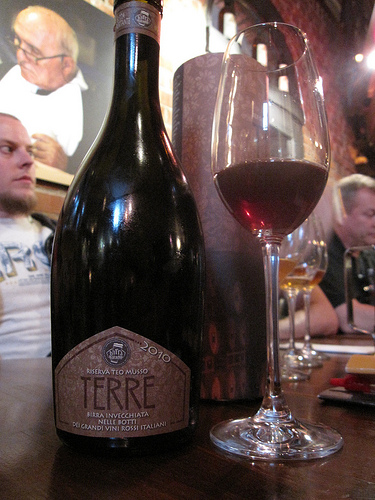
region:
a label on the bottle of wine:
[53, 331, 193, 437]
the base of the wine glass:
[213, 408, 344, 458]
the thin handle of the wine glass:
[253, 242, 291, 409]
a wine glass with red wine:
[209, 19, 340, 460]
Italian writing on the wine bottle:
[67, 366, 167, 432]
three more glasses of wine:
[270, 226, 329, 377]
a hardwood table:
[0, 330, 373, 498]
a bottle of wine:
[50, 1, 215, 452]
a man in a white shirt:
[0, 111, 68, 353]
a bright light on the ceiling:
[358, 41, 374, 71]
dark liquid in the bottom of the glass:
[212, 146, 331, 246]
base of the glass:
[208, 404, 348, 462]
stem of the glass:
[257, 246, 301, 413]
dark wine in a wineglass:
[209, 24, 346, 472]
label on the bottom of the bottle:
[39, 318, 200, 446]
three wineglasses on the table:
[262, 205, 341, 391]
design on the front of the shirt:
[1, 231, 61, 296]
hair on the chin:
[1, 190, 39, 214]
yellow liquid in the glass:
[272, 254, 293, 284]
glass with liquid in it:
[211, 10, 334, 490]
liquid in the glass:
[221, 155, 304, 212]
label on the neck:
[111, 3, 161, 33]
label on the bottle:
[57, 326, 186, 436]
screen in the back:
[0, 10, 114, 160]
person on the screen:
[4, 7, 85, 147]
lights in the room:
[338, 33, 374, 63]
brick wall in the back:
[299, 12, 353, 135]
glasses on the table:
[280, 213, 333, 391]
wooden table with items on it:
[4, 361, 368, 494]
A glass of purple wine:
[201, 16, 351, 470]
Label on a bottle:
[46, 318, 196, 439]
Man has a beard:
[0, 108, 45, 218]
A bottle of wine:
[41, 0, 210, 465]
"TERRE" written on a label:
[69, 366, 159, 412]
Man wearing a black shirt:
[315, 167, 369, 335]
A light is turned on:
[348, 44, 372, 77]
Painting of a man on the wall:
[0, 0, 113, 195]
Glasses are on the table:
[200, 12, 350, 469]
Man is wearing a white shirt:
[0, 108, 56, 363]